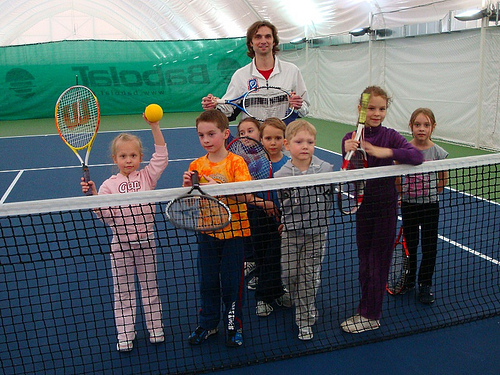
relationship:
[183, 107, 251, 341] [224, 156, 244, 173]
boy has on a shirt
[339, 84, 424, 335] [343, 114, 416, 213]
girl wearing track suit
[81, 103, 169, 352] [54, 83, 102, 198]
child holding racket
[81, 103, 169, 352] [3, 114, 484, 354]
child on court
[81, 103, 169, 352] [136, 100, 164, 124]
child holding ball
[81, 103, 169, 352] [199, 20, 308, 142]
child with coach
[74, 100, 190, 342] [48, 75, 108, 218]
boy holding racket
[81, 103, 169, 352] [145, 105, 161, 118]
child holding ball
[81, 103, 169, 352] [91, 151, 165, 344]
child wearing suit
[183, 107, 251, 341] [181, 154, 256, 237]
boy wearing shirt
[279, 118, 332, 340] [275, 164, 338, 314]
boy wearing suit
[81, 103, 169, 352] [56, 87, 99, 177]
child holding racket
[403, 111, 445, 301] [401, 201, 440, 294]
girl wearing pants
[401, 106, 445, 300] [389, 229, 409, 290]
girl holding racket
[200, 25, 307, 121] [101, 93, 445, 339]
man behind group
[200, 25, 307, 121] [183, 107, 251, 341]
man behind boy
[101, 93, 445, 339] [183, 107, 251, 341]
group of boy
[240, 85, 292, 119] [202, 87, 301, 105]
racket in hands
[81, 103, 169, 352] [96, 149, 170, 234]
child wearing sweater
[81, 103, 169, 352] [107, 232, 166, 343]
child wearing pants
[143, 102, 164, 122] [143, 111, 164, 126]
ball in hand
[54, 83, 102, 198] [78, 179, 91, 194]
racket in hand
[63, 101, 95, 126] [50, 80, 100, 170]
letter on racket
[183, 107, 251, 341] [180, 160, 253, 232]
boy with shirt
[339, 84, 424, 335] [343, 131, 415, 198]
girl with shirt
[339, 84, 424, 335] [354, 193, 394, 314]
girl with pants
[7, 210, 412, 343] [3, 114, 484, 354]
net on a court